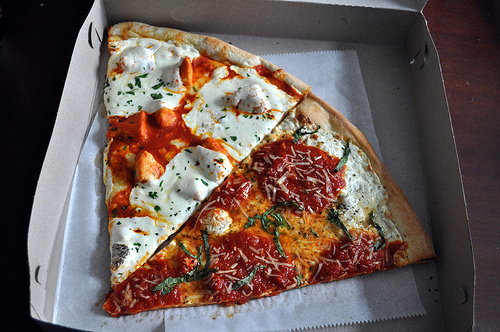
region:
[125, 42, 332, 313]
the pizza is sliced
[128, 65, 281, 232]
the pizza is sliced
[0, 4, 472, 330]
a cardboard box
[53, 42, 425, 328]
a piece of wax paper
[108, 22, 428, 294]
two slices of pizze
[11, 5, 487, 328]
a wooden table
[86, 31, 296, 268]
a slice of cheese pizza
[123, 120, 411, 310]
a slice of pepperoni pizza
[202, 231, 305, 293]
pepperoni on the slice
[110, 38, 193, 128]
globs of cheese on the slice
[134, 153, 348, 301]
sprinkles of extra cheese on the pizza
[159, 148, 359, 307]
shredded parsley on the pizza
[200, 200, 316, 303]
the pizza is red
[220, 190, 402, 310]
the pizza is red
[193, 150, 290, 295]
the pizza is red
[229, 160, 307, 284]
the pizza is red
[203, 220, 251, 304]
the pizza is red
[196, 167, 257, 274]
the pizza is red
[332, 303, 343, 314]
the tissue is white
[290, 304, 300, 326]
the tissue is white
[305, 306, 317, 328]
the tissue is white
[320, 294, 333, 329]
the tissue is white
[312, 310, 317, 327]
the tissue is white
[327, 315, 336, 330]
the tissue is white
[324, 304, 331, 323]
the tissue is white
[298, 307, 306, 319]
the tissue is white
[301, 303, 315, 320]
the tissue is white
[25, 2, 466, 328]
pizza slices inside box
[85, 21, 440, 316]
two slices with different toppings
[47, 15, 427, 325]
white paper between box and pizza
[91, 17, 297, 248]
large blobs of melted white cheese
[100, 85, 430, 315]
green and white shreds over tomato sauce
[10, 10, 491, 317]
cardboard box on top of dark brown surface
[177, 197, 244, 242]
puffy white bubble of cheese on edge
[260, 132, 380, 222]
melted cheese next to circle of tomato sauce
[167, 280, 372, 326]
wrinkles and serrated edge of paper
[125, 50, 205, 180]
pebble-like ingredient covered in tomato sauce